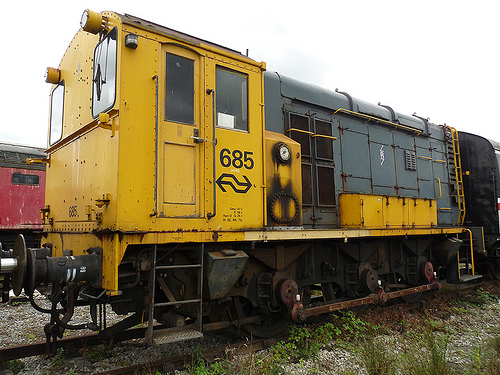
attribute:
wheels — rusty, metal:
[214, 247, 312, 345]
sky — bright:
[2, 3, 499, 163]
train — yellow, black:
[38, 8, 499, 319]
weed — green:
[275, 314, 330, 363]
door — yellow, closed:
[149, 43, 207, 224]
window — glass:
[160, 53, 198, 130]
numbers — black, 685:
[217, 145, 258, 174]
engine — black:
[451, 138, 496, 235]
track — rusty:
[3, 273, 494, 369]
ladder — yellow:
[441, 119, 467, 224]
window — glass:
[216, 64, 250, 127]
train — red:
[1, 142, 51, 242]